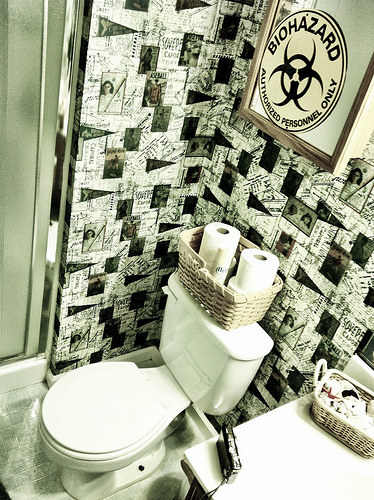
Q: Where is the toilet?
A: In the bathroom.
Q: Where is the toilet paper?
A: In a basket.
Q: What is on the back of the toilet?
A: A basket.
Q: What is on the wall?
A: Wallpaper.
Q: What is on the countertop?
A: A basket.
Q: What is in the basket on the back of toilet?
A: Toilet paper.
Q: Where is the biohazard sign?
A: Behind the toilet.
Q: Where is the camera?
A: On the sink.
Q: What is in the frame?
A: A glass shower door.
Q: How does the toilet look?
A: It is white.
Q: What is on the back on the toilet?
A: A wicker basket.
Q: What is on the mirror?
A: A biohazard symbol.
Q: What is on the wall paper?
A: A pattern.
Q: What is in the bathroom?
A: A white toilet.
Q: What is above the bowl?
A: A toilet tank.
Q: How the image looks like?
A: Good.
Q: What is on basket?
A: Toilet papers.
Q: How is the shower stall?
A: Glass.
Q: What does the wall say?
A: Biohazard.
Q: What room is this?
A: Bathroom.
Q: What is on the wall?
A: Wallpaper.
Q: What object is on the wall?
A: Mirror.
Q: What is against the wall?
A: Toilet.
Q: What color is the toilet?
A: White.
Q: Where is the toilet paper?
A: On the toilet.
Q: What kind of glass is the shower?
A: Plexiglass.